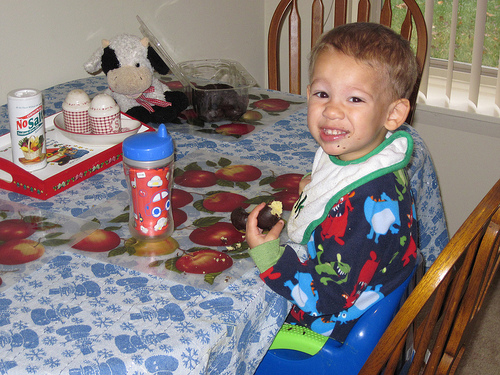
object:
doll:
[82, 32, 188, 124]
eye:
[348, 97, 364, 102]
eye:
[313, 91, 327, 99]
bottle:
[61, 89, 91, 134]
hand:
[245, 202, 283, 247]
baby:
[245, 22, 454, 344]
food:
[7, 89, 46, 169]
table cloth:
[0, 70, 449, 373]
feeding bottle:
[121, 124, 178, 243]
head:
[305, 20, 419, 157]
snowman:
[0, 283, 183, 351]